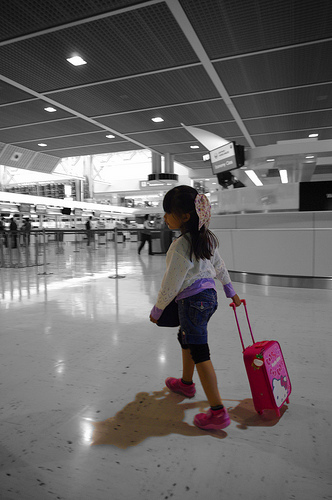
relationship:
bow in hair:
[192, 184, 214, 229] [161, 180, 223, 265]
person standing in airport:
[9, 218, 18, 251] [4, 2, 329, 492]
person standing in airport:
[84, 215, 92, 246] [4, 2, 329, 492]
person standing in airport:
[22, 217, 31, 245] [4, 2, 329, 492]